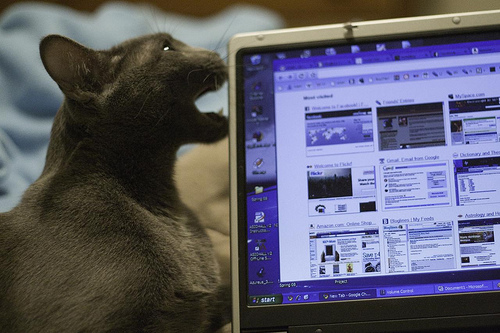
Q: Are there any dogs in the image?
A: No, there are no dogs.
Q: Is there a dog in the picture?
A: No, there are no dogs.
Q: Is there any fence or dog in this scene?
A: No, there are no dogs or fences.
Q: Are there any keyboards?
A: Yes, there is a keyboard.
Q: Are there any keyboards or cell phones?
A: Yes, there is a keyboard.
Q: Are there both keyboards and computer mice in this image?
A: No, there is a keyboard but no computer mice.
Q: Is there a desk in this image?
A: No, there are no desks.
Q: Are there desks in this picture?
A: No, there are no desks.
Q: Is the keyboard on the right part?
A: Yes, the keyboard is on the right of the image.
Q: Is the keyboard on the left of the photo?
A: No, the keyboard is on the right of the image.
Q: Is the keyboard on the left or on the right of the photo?
A: The keyboard is on the right of the image.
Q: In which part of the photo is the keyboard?
A: The keyboard is on the right of the image.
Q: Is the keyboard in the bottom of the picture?
A: Yes, the keyboard is in the bottom of the image.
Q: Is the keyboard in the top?
A: No, the keyboard is in the bottom of the image.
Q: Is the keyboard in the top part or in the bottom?
A: The keyboard is in the bottom of the image.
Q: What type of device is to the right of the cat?
A: The device is a keyboard.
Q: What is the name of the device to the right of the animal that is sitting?
A: The device is a keyboard.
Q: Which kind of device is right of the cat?
A: The device is a keyboard.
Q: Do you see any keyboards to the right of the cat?
A: Yes, there is a keyboard to the right of the cat.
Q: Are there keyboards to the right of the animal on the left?
A: Yes, there is a keyboard to the right of the cat.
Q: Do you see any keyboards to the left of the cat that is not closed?
A: No, the keyboard is to the right of the cat.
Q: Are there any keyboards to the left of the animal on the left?
A: No, the keyboard is to the right of the cat.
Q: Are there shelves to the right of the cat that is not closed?
A: No, there is a keyboard to the right of the cat.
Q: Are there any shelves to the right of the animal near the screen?
A: No, there is a keyboard to the right of the cat.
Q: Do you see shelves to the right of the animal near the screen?
A: No, there is a keyboard to the right of the cat.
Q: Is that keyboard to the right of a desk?
A: No, the keyboard is to the right of the cat.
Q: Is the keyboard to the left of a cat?
A: No, the keyboard is to the right of a cat.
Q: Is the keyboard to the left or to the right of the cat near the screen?
A: The keyboard is to the right of the cat.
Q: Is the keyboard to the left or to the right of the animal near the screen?
A: The keyboard is to the right of the cat.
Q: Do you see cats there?
A: Yes, there is a cat.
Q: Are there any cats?
A: Yes, there is a cat.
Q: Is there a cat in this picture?
A: Yes, there is a cat.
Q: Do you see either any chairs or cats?
A: Yes, there is a cat.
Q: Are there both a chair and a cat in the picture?
A: No, there is a cat but no chairs.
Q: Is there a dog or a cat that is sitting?
A: Yes, the cat is sitting.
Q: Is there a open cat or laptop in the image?
A: Yes, there is an open cat.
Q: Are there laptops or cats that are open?
A: Yes, the cat is open.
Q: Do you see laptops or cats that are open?
A: Yes, the cat is open.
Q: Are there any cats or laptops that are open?
A: Yes, the cat is open.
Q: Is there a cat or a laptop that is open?
A: Yes, the cat is open.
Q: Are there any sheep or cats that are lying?
A: Yes, the cat is lying.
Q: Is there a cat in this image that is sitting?
A: Yes, there is a cat that is sitting.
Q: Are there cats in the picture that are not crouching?
A: Yes, there is a cat that is sitting.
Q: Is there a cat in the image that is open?
A: Yes, there is an open cat.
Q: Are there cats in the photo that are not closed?
A: Yes, there is a open cat.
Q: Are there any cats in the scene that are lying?
A: Yes, there is a cat that is lying.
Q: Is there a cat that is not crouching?
A: Yes, there is a cat that is lying.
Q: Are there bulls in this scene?
A: No, there are no bulls.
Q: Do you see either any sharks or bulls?
A: No, there are no bulls or sharks.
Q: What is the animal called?
A: The animal is a cat.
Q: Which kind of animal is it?
A: The animal is a cat.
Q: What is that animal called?
A: This is a cat.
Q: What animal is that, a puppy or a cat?
A: This is a cat.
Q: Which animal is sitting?
A: The animal is a cat.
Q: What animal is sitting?
A: The animal is a cat.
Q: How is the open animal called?
A: The animal is a cat.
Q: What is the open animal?
A: The animal is a cat.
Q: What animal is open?
A: The animal is a cat.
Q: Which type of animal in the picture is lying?
A: The animal is a cat.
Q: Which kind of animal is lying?
A: The animal is a cat.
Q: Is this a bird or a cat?
A: This is a cat.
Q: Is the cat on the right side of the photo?
A: No, the cat is on the left of the image.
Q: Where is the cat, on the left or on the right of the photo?
A: The cat is on the left of the image.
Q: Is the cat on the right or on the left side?
A: The cat is on the left of the image.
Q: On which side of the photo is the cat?
A: The cat is on the left of the image.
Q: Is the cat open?
A: Yes, the cat is open.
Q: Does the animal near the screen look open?
A: Yes, the cat is open.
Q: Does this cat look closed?
A: No, the cat is open.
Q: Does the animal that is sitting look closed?
A: No, the cat is open.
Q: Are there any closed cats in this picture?
A: No, there is a cat but it is open.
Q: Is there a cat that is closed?
A: No, there is a cat but it is open.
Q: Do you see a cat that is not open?
A: No, there is a cat but it is open.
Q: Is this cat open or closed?
A: The cat is open.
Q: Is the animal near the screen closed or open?
A: The cat is open.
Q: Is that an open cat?
A: Yes, that is an open cat.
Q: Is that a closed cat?
A: No, that is an open cat.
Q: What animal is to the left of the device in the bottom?
A: The animal is a cat.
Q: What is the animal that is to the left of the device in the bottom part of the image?
A: The animal is a cat.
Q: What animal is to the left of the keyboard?
A: The animal is a cat.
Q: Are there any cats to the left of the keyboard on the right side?
A: Yes, there is a cat to the left of the keyboard.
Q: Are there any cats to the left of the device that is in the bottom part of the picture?
A: Yes, there is a cat to the left of the keyboard.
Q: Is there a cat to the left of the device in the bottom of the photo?
A: Yes, there is a cat to the left of the keyboard.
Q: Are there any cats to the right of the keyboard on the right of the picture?
A: No, the cat is to the left of the keyboard.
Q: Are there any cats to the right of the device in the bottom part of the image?
A: No, the cat is to the left of the keyboard.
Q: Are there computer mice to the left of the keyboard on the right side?
A: No, there is a cat to the left of the keyboard.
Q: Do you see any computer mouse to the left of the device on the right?
A: No, there is a cat to the left of the keyboard.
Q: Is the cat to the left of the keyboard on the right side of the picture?
A: Yes, the cat is to the left of the keyboard.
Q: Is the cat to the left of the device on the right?
A: Yes, the cat is to the left of the keyboard.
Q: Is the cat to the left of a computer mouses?
A: No, the cat is to the left of the keyboard.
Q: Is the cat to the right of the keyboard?
A: No, the cat is to the left of the keyboard.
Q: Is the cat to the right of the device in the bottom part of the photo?
A: No, the cat is to the left of the keyboard.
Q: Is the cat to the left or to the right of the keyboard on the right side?
A: The cat is to the left of the keyboard.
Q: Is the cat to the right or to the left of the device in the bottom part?
A: The cat is to the left of the keyboard.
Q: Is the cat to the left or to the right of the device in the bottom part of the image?
A: The cat is to the left of the keyboard.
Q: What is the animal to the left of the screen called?
A: The animal is a cat.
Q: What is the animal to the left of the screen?
A: The animal is a cat.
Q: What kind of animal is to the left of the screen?
A: The animal is a cat.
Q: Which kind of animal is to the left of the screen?
A: The animal is a cat.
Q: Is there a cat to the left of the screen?
A: Yes, there is a cat to the left of the screen.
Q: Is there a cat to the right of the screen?
A: No, the cat is to the left of the screen.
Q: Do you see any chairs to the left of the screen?
A: No, there is a cat to the left of the screen.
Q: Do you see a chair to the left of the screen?
A: No, there is a cat to the left of the screen.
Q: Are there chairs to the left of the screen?
A: No, there is a cat to the left of the screen.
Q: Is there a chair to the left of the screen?
A: No, there is a cat to the left of the screen.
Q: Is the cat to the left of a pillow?
A: No, the cat is to the left of a screen.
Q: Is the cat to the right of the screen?
A: No, the cat is to the left of the screen.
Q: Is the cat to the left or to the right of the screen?
A: The cat is to the left of the screen.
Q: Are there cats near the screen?
A: Yes, there is a cat near the screen.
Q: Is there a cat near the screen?
A: Yes, there is a cat near the screen.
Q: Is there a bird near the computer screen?
A: No, there is a cat near the screen.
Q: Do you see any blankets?
A: Yes, there is a blanket.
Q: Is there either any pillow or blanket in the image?
A: Yes, there is a blanket.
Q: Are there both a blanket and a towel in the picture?
A: No, there is a blanket but no towels.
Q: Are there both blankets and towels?
A: No, there is a blanket but no towels.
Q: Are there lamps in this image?
A: No, there are no lamps.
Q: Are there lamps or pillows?
A: No, there are no lamps or pillows.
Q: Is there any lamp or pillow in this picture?
A: No, there are no lamps or pillows.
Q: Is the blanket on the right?
A: No, the blanket is on the left of the image.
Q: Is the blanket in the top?
A: Yes, the blanket is in the top of the image.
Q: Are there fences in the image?
A: No, there are no fences.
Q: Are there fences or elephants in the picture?
A: No, there are no fences or elephants.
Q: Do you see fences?
A: No, there are no fences.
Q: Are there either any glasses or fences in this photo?
A: No, there are no fences or glasses.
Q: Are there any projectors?
A: No, there are no projectors.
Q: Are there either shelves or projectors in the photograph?
A: No, there are no projectors or shelves.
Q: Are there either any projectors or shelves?
A: No, there are no projectors or shelves.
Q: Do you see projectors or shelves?
A: No, there are no projectors or shelves.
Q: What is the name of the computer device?
A: The device is a screen.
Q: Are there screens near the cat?
A: Yes, there is a screen near the cat.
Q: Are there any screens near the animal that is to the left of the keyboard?
A: Yes, there is a screen near the cat.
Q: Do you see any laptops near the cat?
A: No, there is a screen near the cat.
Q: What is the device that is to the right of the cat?
A: The device is a screen.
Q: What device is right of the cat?
A: The device is a screen.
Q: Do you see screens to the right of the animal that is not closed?
A: Yes, there is a screen to the right of the cat.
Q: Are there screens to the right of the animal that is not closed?
A: Yes, there is a screen to the right of the cat.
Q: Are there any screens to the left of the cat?
A: No, the screen is to the right of the cat.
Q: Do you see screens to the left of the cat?
A: No, the screen is to the right of the cat.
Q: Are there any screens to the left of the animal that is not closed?
A: No, the screen is to the right of the cat.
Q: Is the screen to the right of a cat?
A: Yes, the screen is to the right of a cat.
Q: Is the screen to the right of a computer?
A: No, the screen is to the right of a cat.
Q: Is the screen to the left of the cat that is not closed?
A: No, the screen is to the right of the cat.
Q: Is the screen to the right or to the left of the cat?
A: The screen is to the right of the cat.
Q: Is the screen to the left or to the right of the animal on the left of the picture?
A: The screen is to the right of the cat.